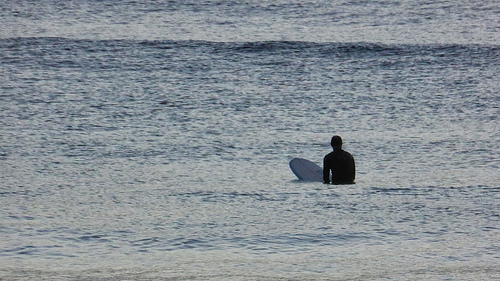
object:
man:
[321, 135, 355, 184]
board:
[288, 157, 331, 181]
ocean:
[114, 109, 171, 143]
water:
[235, 81, 266, 109]